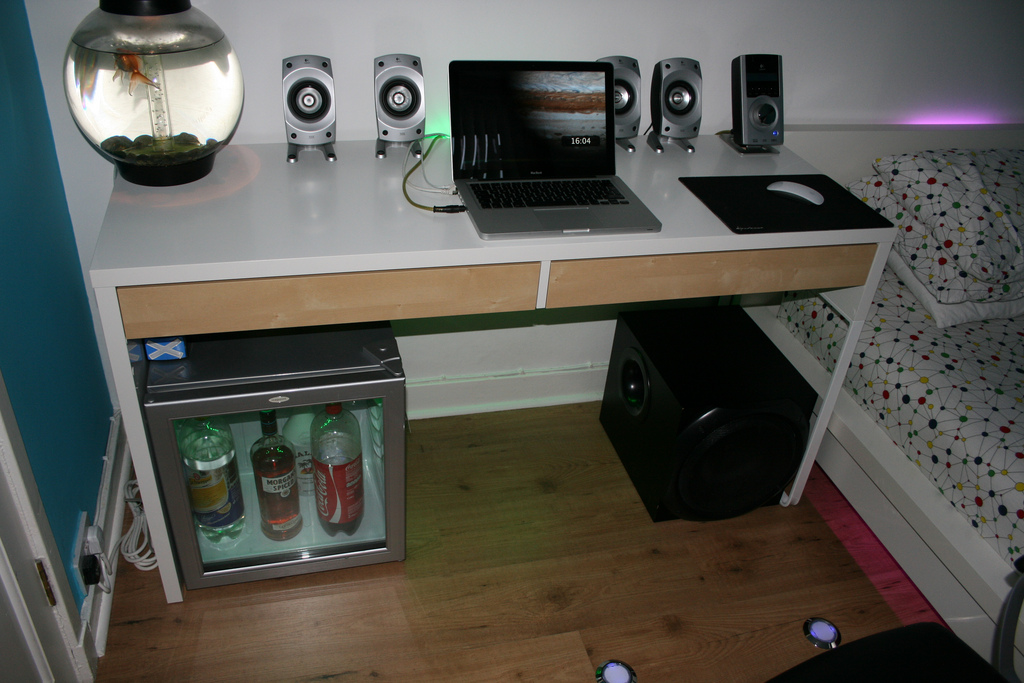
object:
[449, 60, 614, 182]
screen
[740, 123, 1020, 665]
bed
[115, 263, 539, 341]
drawer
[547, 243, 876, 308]
drawer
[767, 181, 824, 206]
mouse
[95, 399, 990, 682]
floor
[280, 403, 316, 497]
bottle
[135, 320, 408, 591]
fridge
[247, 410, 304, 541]
bottle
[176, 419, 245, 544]
bottle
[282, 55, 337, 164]
speaker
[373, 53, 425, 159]
speaker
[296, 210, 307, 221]
table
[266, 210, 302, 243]
table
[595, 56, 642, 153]
speaker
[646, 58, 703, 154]
speaker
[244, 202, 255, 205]
table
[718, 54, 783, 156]
speaker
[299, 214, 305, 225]
table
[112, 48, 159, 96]
goldfish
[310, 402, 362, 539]
coca cola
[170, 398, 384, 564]
glass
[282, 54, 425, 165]
speakers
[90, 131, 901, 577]
desk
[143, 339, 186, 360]
flag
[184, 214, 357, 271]
table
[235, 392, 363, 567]
chest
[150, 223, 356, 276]
table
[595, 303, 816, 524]
sound system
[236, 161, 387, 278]
table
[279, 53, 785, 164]
speaker system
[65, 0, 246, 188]
aquarium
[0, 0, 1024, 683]
room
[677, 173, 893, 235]
mouse pad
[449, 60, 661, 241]
laptop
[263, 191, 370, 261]
table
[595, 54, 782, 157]
speakers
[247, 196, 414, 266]
table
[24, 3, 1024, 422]
wall